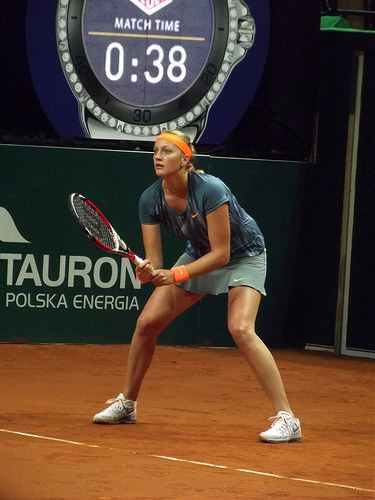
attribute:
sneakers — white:
[94, 393, 304, 447]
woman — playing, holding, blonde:
[94, 130, 305, 440]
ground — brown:
[2, 341, 374, 499]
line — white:
[1, 418, 374, 499]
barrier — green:
[2, 140, 314, 362]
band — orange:
[171, 263, 192, 284]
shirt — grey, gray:
[132, 175, 277, 260]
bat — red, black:
[70, 189, 141, 285]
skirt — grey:
[167, 254, 269, 298]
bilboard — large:
[24, 5, 274, 144]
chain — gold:
[157, 179, 196, 215]